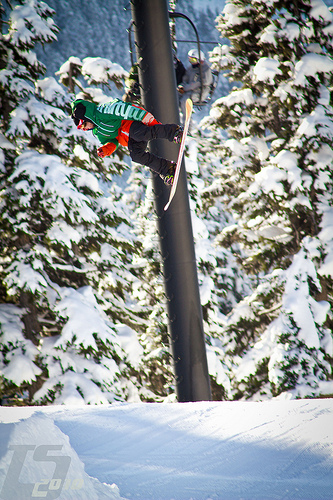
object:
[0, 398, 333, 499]
snow